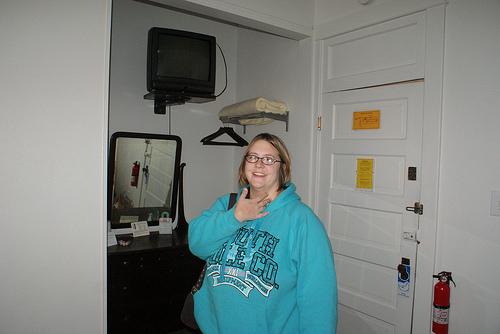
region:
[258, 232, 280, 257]
black outlined letter on shirt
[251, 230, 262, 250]
black outlined letter on shirt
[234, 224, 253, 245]
black outlined letter on shirt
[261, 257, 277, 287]
black outlined letter on shirt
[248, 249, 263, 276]
black outlined letter on shirt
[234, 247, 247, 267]
black outlined letter on shirt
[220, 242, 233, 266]
black outlined letter on shirt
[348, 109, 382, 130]
yellow sign on door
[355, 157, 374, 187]
yellow sign on door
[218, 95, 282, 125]
folded tan colored towel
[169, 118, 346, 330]
person wearing eye glass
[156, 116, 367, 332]
person wearing a teal hoodie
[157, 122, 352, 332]
person carrying bag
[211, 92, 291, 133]
towels on a metal shelf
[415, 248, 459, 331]
a fire hydrant mounted on wall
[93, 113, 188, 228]
mirror on a table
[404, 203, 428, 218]
a latch lock from the inside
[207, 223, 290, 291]
front design of a hoodie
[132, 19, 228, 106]
a television set mounted on top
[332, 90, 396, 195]
papers on a door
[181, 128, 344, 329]
The woman in the sweatshirt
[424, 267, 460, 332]
The fire extinguisher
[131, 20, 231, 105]
The tv mounted on the wall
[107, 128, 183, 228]
The mirror above the dresser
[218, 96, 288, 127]
The yellow blanket on the metal shelf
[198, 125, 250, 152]
The hangers on the metal shelf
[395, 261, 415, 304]
The door hanger on the handle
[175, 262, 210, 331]
The purse the woman is carrying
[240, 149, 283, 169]
The woman's seeing glasses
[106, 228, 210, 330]
The dresser the mirror is on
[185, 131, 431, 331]
a lady is standing in front of a door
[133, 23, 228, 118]
a tv is up on the wall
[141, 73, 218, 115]
the tv is on a black shelf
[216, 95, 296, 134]
a blanket is on a shelf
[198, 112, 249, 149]
hangers are hanging on the shelf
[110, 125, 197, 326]
a mirror is on a dresser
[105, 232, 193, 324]
the dresser has dark wood drawers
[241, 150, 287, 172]
the girl is wearing eyeglasses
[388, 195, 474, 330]
a fire extinguisher is by the door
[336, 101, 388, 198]
signs are on the back of the door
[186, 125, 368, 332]
Woman staniding in room.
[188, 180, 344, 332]
Woman dressed in light blue sweatshirt with hood.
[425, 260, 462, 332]
Fire extinguisher hanging next to door.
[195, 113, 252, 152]
Hangers hanging on rack behind door.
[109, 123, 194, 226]
Adjustable mirror on dresser.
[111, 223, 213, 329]
Brown dresser behind standing woman.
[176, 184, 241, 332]
Woman carrying purse over shoulder.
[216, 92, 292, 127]
Blanket folded on rack behind door.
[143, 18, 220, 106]
Tv mounted on wall over dresser.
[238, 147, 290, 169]
Woman wearing eyeglasses over eyes.